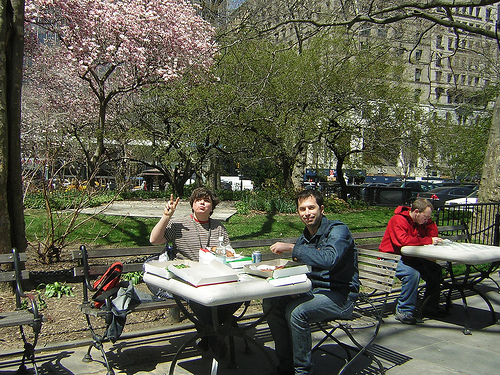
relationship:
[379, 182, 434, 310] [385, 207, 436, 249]
man wearing red sweater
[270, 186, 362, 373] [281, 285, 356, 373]
man wearing jeans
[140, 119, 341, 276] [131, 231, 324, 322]
two males at table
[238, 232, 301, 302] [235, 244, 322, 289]
box of food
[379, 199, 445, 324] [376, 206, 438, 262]
man wearing red sweater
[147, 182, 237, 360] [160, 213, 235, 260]
boy wearing striped shirt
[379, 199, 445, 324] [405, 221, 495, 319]
man at table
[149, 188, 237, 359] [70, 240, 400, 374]
boy on bench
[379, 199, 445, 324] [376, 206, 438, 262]
man in red sweater